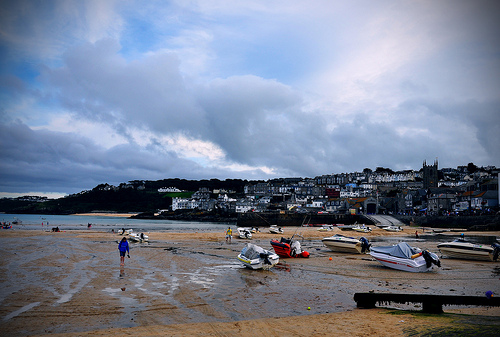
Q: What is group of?
A: Buildings.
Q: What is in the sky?
A: Clouds.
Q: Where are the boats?
A: Sand.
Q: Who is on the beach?
A: Group.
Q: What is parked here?
A: Boats.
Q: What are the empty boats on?
A: The beach.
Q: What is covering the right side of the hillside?
A: Houses.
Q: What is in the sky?
A: Clouds.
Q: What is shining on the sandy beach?
A: Water.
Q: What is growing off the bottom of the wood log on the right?
A: Moss.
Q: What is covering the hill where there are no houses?
A: Trees.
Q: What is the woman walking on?
A: The beach.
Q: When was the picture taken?
A: Daytime.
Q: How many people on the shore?
A: Two.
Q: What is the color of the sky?
A: Blue, white and gray.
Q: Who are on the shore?
A: People.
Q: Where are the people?
A: At the beach.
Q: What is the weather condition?
A: Overcast.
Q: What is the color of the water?
A: Blue.